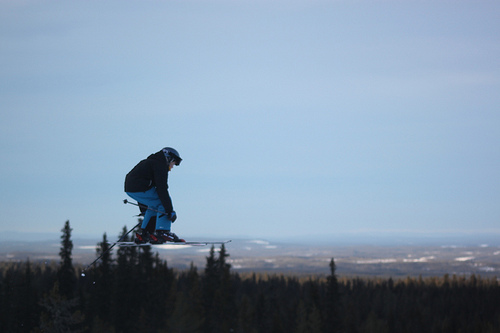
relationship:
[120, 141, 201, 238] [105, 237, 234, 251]
person on skis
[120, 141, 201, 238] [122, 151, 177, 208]
person has coat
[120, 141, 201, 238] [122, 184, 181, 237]
person has pants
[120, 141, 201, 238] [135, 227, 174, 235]
person has shoes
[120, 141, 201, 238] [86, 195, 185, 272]
person holds ski poles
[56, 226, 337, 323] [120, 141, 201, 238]
trees behind person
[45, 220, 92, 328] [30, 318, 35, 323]
tree in corner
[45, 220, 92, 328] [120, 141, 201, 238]
tree by man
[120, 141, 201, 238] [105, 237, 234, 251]
person wearing skis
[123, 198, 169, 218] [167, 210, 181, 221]
ski pole in hand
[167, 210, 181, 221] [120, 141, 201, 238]
hand of person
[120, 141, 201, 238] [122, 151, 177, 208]
person wearing jacket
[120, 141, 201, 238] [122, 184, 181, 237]
person wearing pants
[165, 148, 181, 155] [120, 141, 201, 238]
helmet of person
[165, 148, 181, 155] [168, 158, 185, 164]
helmet and goggles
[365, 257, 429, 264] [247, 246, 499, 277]
snow on land